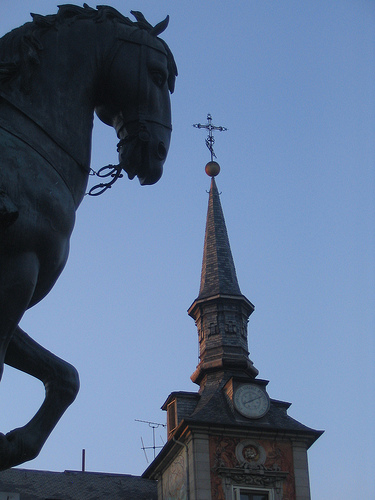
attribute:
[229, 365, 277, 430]
clock — visibley, white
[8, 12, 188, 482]
horse — statue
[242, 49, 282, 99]
sky — blue